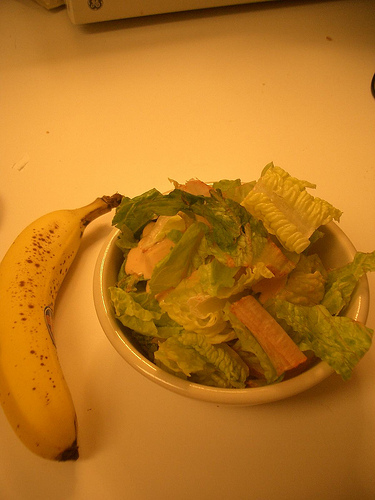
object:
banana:
[1, 193, 122, 463]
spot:
[30, 350, 38, 356]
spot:
[46, 228, 54, 235]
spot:
[27, 303, 35, 309]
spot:
[31, 385, 38, 393]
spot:
[35, 262, 41, 268]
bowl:
[94, 182, 370, 408]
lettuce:
[240, 166, 343, 254]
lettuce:
[275, 300, 374, 383]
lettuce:
[150, 223, 206, 298]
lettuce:
[111, 188, 211, 236]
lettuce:
[153, 337, 207, 377]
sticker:
[42, 307, 56, 350]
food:
[108, 163, 373, 387]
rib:
[255, 181, 313, 238]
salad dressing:
[125, 221, 178, 281]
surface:
[1, 27, 374, 163]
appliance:
[39, 0, 269, 27]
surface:
[0, 0, 374, 499]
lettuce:
[229, 295, 309, 374]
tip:
[100, 192, 127, 208]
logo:
[88, 1, 104, 11]